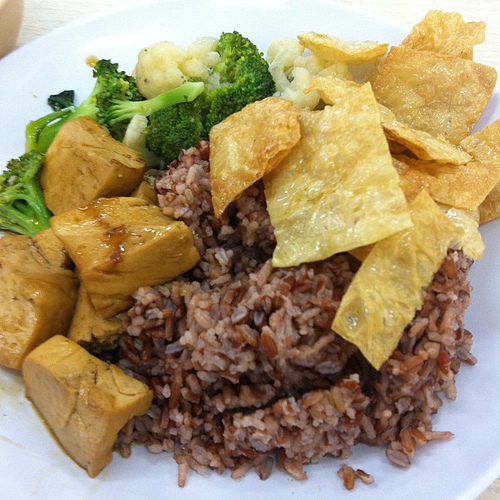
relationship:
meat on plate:
[25, 142, 240, 453] [8, 19, 473, 498]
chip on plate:
[330, 186, 458, 371] [327, 386, 490, 496]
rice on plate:
[130, 265, 446, 465] [8, 19, 473, 498]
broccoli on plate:
[1, 30, 280, 234] [32, 7, 237, 49]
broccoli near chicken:
[1, 30, 280, 234] [2, 107, 200, 479]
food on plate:
[8, 42, 483, 467] [8, 19, 473, 498]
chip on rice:
[330, 186, 458, 371] [205, 274, 382, 387]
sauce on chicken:
[88, 198, 160, 273] [45, 180, 200, 319]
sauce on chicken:
[88, 198, 160, 273] [20, 332, 156, 478]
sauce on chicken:
[88, 198, 160, 273] [2, 225, 79, 373]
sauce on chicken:
[88, 198, 160, 273] [36, 112, 151, 217]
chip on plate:
[330, 186, 458, 371] [440, 360, 498, 479]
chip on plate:
[334, 186, 460, 368] [440, 360, 498, 479]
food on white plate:
[8, 42, 483, 467] [40, 15, 200, 80]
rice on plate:
[88, 140, 478, 488] [8, 19, 473, 498]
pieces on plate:
[329, 458, 368, 495] [9, 435, 496, 499]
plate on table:
[1, 0, 498, 498] [4, 2, 144, 86]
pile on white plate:
[122, 143, 475, 485] [2, 216, 498, 498]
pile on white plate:
[122, 143, 475, 485] [3, 0, 497, 171]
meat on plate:
[25, 142, 240, 453] [34, 37, 464, 474]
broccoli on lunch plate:
[1, 30, 280, 234] [8, 19, 473, 498]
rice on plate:
[88, 140, 478, 488] [1, 0, 498, 498]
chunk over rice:
[5, 235, 72, 382] [146, 237, 392, 398]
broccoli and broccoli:
[1, 30, 280, 234] [79, 67, 144, 125]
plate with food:
[1, 0, 498, 498] [3, 8, 498, 491]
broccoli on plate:
[1, 30, 280, 234] [8, 19, 473, 498]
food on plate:
[8, 42, 483, 467] [1, 0, 498, 498]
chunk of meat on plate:
[5, 235, 72, 382] [8, 19, 473, 498]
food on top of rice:
[8, 42, 483, 467] [181, 283, 328, 440]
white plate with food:
[40, 15, 200, 80] [22, 334, 147, 476]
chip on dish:
[330, 186, 458, 371] [9, 14, 101, 81]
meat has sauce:
[25, 142, 240, 453] [72, 200, 145, 266]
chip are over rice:
[330, 186, 458, 371] [88, 140, 478, 488]